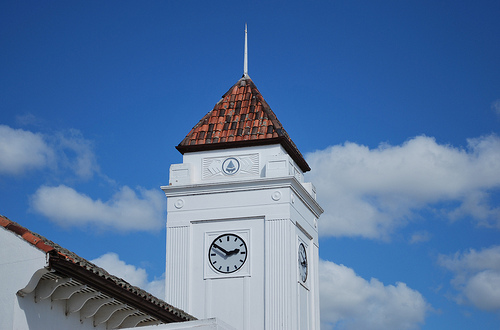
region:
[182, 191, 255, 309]
a clock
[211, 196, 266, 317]
a clock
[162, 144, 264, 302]
a clock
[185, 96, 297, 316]
a clock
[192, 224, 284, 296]
a clock on building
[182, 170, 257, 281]
a clock on building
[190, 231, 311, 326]
a clock on building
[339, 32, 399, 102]
part of the sky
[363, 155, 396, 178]
part of a cloud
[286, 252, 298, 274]
edge of a tower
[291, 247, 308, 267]
part of a clock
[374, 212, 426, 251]
edge of a cloud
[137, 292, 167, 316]
edge of a roof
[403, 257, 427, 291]
part of the sky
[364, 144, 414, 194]
part of a cloud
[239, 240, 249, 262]
edge of a clock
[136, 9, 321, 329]
a white clock tower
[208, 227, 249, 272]
the clock has black hands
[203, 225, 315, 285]
two clocks on the tower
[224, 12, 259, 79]
the towers has a steeple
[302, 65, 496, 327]
the sky is partly cloudy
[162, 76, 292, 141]
the roof of the steeple is shingled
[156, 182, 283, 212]
the tower has decorative trim work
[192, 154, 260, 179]
a logo on the tower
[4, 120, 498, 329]
the sky is equally blue and cloudy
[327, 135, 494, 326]
the clouds are white and fluffy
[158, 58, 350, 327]
large white clock tower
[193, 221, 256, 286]
extremely large clock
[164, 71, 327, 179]
small tiled roof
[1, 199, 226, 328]
medium sized tiled roof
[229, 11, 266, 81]
small antenea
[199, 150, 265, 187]
artistic design on clock tower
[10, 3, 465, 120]
clear blue sky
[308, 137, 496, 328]
scattered white clouds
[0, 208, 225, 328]
building with a clock tower attached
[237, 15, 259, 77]
very top of a clock tower